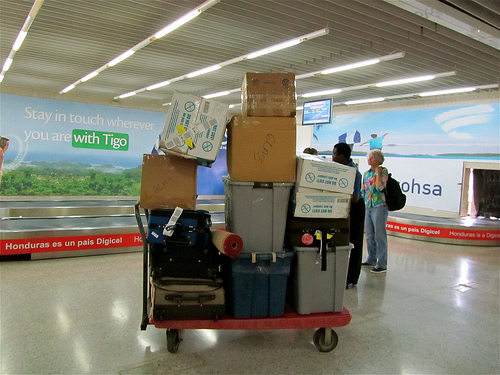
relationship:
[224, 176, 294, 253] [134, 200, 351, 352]
bin on trolley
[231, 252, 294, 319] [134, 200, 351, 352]
bin on trolley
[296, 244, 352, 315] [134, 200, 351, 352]
bin on trolley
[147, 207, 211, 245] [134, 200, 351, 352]
suitcase on trolley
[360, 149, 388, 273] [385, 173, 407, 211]
woman with backpack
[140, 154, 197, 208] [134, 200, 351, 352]
box on trolley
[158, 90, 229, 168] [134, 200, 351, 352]
box on trolley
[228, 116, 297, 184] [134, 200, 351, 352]
box on trolley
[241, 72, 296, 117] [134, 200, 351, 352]
box on trolley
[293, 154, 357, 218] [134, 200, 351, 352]
box on trolley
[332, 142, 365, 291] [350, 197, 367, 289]
man with pants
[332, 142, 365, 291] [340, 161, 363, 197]
man with shirt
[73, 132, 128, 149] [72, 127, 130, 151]
lettering in box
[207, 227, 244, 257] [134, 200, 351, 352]
mat on trolley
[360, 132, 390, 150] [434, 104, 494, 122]
boy pointing at cloud